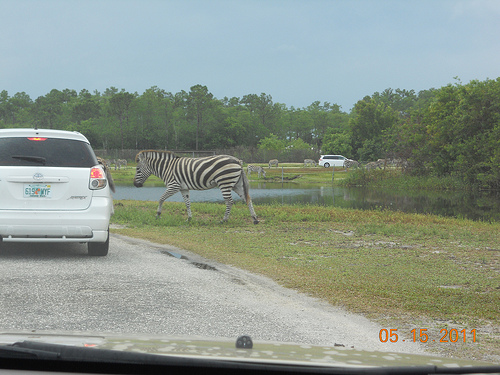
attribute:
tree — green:
[396, 78, 484, 215]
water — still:
[111, 177, 471, 217]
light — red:
[28, 134, 47, 142]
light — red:
[88, 162, 106, 178]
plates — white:
[21, 180, 52, 197]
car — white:
[4, 123, 114, 257]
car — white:
[314, 150, 354, 170]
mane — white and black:
[136, 147, 182, 157]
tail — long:
[240, 162, 250, 200]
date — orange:
[378, 326, 480, 346]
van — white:
[318, 151, 358, 170]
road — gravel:
[1, 228, 448, 372]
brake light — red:
[90, 165, 102, 178]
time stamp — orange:
[378, 327, 477, 345]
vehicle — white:
[318, 151, 355, 169]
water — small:
[115, 183, 498, 223]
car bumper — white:
[0, 216, 110, 246]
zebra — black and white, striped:
[133, 150, 262, 228]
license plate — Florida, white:
[22, 183, 53, 200]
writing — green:
[24, 188, 49, 195]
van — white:
[1, 125, 114, 256]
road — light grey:
[38, 244, 270, 340]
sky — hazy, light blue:
[1, 6, 435, 93]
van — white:
[312, 150, 359, 171]